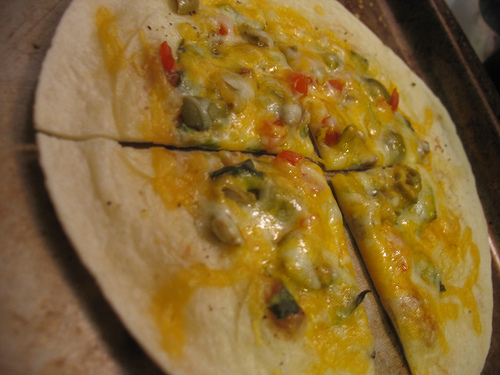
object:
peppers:
[271, 150, 305, 174]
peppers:
[367, 77, 391, 102]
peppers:
[390, 87, 400, 111]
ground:
[330, 165, 493, 375]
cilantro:
[211, 158, 264, 179]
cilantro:
[348, 289, 371, 315]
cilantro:
[260, 80, 287, 103]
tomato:
[324, 130, 340, 146]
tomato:
[327, 79, 343, 93]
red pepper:
[291, 72, 313, 95]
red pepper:
[220, 24, 229, 35]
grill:
[3, 0, 498, 375]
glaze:
[144, 11, 480, 371]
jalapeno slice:
[392, 166, 422, 204]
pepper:
[160, 41, 175, 71]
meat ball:
[280, 228, 323, 290]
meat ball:
[210, 207, 244, 246]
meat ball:
[282, 100, 302, 125]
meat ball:
[176, 0, 200, 15]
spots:
[148, 22, 173, 37]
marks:
[5, 285, 95, 375]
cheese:
[33, 0, 493, 375]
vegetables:
[351, 50, 369, 71]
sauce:
[92, 0, 483, 371]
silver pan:
[380, 120, 464, 244]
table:
[1, 0, 500, 375]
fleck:
[107, 201, 112, 204]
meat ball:
[181, 94, 229, 129]